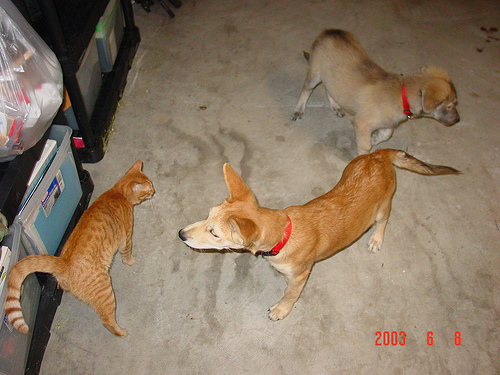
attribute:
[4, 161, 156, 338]
cat — orange, brown, nervous, watching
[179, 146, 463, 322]
dog — brown, looking, gray, inside, interested, waiting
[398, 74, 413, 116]
collar — red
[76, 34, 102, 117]
container — plastic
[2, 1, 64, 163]
bag — plastic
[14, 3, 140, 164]
bookshelf — black, plastic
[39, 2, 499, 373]
floor — gray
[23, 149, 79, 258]
tray — blue